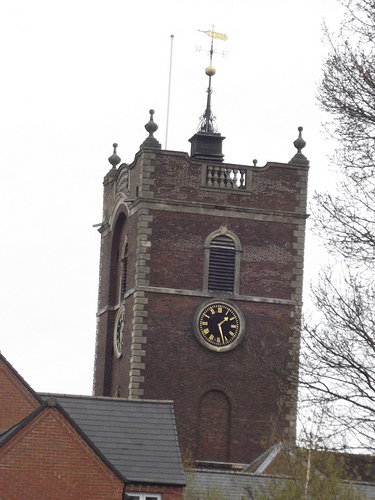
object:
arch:
[195, 388, 233, 467]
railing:
[201, 161, 252, 194]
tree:
[297, 278, 374, 459]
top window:
[124, 482, 177, 498]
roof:
[42, 394, 184, 482]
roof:
[94, 112, 314, 227]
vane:
[204, 36, 217, 110]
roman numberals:
[200, 305, 239, 345]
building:
[0, 353, 191, 500]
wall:
[171, 326, 290, 473]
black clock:
[195, 298, 247, 349]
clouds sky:
[244, 0, 375, 211]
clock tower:
[90, 42, 312, 473]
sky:
[0, 0, 375, 292]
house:
[1, 347, 186, 499]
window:
[121, 491, 163, 499]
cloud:
[0, 0, 374, 452]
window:
[199, 232, 245, 298]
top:
[96, 145, 322, 213]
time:
[192, 297, 245, 351]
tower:
[90, 68, 309, 472]